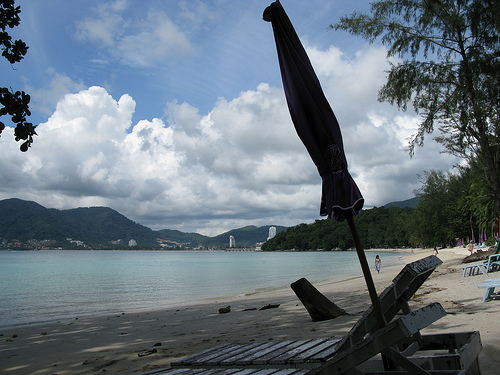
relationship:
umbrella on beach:
[256, 3, 436, 373] [5, 244, 499, 372]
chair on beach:
[165, 254, 481, 374] [295, 241, 469, 370]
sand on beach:
[2, 334, 152, 371] [5, 244, 499, 372]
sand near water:
[207, 303, 337, 353] [0, 247, 412, 327]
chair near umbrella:
[132, 301, 445, 374] [257, 0, 396, 326]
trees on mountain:
[246, 191, 487, 261] [245, 197, 430, 276]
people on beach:
[370, 251, 382, 273] [5, 244, 499, 372]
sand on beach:
[2, 314, 158, 371] [5, 244, 499, 372]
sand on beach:
[369, 245, 498, 374] [5, 244, 499, 372]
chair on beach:
[173, 265, 472, 373] [351, 231, 489, 336]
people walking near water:
[375, 254, 382, 273] [50, 246, 135, 318]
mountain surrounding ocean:
[3, 192, 281, 258] [5, 248, 405, 321]